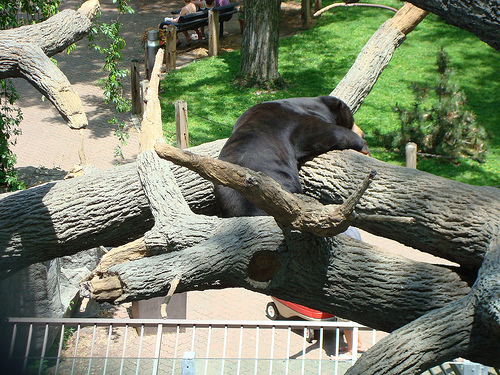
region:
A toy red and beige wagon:
[261, 293, 338, 338]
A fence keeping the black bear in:
[8, 317, 465, 373]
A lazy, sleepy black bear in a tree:
[216, 90, 366, 232]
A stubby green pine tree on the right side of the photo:
[396, 67, 490, 168]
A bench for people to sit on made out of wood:
[158, 12, 238, 41]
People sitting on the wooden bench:
[163, 3, 233, 29]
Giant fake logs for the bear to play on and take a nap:
[4, 63, 494, 373]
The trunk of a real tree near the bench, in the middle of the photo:
[240, 2, 285, 92]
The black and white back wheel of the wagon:
[265, 303, 277, 318]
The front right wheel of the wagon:
[306, 327, 315, 344]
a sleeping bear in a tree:
[207, 87, 371, 217]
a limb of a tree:
[103, 226, 478, 347]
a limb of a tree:
[359, 141, 499, 247]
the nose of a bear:
[351, 123, 368, 138]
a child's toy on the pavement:
[261, 293, 341, 352]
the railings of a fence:
[15, 310, 338, 371]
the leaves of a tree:
[435, 100, 465, 155]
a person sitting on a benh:
[147, 1, 224, 41]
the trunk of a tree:
[236, 5, 286, 96]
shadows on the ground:
[289, 35, 344, 74]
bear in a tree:
[211, 85, 398, 228]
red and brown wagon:
[268, 300, 348, 356]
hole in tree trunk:
[229, 237, 324, 302]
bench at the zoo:
[166, 9, 253, 41]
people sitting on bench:
[153, 0, 274, 50]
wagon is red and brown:
[261, 298, 346, 341]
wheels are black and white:
[266, 302, 311, 342]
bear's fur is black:
[206, 88, 361, 221]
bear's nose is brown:
[347, 115, 367, 140]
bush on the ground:
[406, 62, 488, 174]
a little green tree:
[392, 52, 481, 157]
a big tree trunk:
[206, 7, 312, 104]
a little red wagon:
[257, 294, 341, 342]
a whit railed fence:
[39, 315, 310, 367]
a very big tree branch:
[51, 148, 213, 255]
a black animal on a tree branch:
[206, 64, 378, 251]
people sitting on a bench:
[144, 0, 265, 47]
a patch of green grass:
[270, 17, 355, 85]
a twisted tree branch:
[161, 120, 419, 266]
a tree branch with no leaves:
[36, 48, 269, 263]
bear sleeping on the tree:
[222, 55, 360, 272]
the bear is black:
[211, 56, 387, 325]